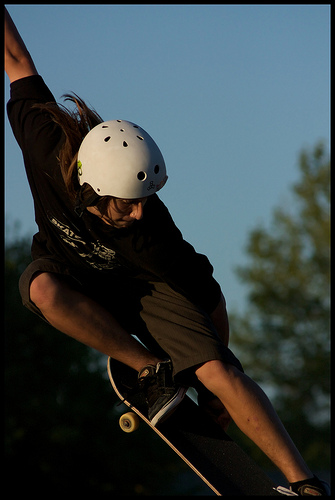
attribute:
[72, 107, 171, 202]
helmet — white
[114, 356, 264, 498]
skateboard — black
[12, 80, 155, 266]
tshirt — black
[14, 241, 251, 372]
shorts — brown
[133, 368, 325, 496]
sneakers — black